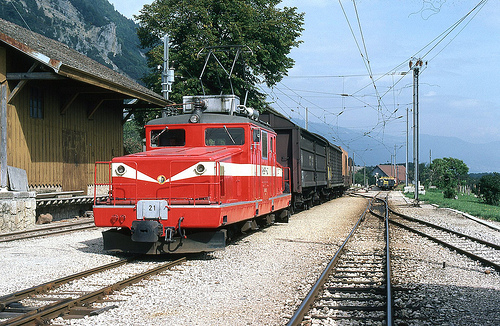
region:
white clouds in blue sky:
[340, 105, 375, 139]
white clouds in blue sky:
[450, 99, 475, 129]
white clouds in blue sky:
[317, 36, 354, 67]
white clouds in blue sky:
[358, 15, 420, 42]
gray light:
[404, 46, 434, 177]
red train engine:
[127, 106, 284, 244]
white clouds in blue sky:
[294, 88, 322, 119]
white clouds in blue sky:
[330, 12, 381, 52]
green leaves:
[182, 16, 252, 60]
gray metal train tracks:
[325, 239, 416, 301]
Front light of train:
[192, 161, 206, 173]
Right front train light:
[115, 161, 125, 174]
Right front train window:
[145, 125, 185, 145]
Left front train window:
[205, 130, 244, 147]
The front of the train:
[89, 102, 293, 251]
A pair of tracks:
[3, 254, 208, 324]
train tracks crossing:
[290, 181, 498, 324]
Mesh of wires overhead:
[260, 45, 422, 162]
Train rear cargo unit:
[257, 105, 350, 201]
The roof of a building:
[0, 20, 174, 107]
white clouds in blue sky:
[314, 13, 331, 45]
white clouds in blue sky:
[312, 52, 340, 72]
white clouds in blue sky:
[290, 83, 329, 109]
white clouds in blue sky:
[351, 123, 366, 144]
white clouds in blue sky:
[369, 5, 396, 35]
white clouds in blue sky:
[401, 19, 413, 32]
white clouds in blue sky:
[431, 52, 469, 83]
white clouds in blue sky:
[449, 80, 496, 98]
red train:
[122, 114, 268, 238]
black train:
[281, 122, 346, 192]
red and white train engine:
[108, 86, 276, 247]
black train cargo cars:
[284, 119, 349, 191]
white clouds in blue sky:
[304, 41, 336, 83]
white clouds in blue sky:
[332, 92, 386, 152]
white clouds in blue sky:
[362, 23, 422, 80]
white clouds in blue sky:
[427, 108, 485, 148]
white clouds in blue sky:
[438, 35, 482, 93]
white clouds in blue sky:
[335, 21, 395, 72]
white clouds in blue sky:
[334, 42, 385, 73]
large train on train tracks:
[91, 103, 395, 247]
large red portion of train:
[60, 86, 311, 260]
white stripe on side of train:
[198, 159, 299, 189]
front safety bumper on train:
[74, 148, 231, 249]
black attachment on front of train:
[134, 211, 158, 238]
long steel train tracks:
[295, 160, 389, 324]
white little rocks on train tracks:
[27, 260, 164, 322]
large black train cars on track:
[266, 105, 376, 213]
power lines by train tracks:
[326, 3, 476, 108]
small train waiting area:
[0, 40, 132, 204]